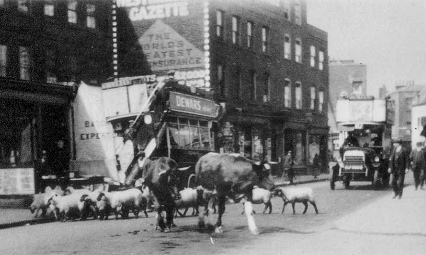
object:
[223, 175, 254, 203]
chest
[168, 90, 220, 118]
sign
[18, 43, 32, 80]
window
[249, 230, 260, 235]
hoof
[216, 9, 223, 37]
window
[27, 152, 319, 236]
animals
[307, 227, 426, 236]
line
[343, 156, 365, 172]
vent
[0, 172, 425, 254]
road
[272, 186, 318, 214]
animals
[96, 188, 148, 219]
sheep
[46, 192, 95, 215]
sheep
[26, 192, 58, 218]
sheep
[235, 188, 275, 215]
sheep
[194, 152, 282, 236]
cow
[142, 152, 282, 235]
cow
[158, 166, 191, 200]
head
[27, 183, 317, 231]
sheep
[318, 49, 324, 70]
window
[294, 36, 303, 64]
window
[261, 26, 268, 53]
window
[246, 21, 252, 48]
window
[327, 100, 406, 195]
car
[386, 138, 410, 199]
man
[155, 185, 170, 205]
chest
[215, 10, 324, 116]
windows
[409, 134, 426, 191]
people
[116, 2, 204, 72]
image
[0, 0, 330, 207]
building